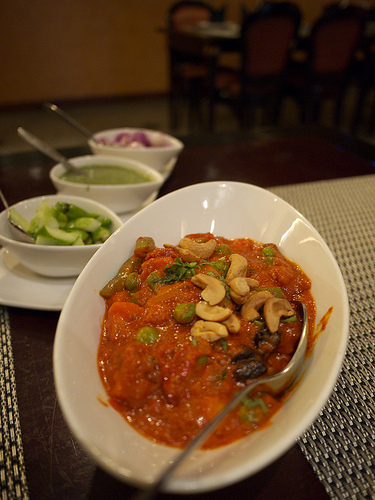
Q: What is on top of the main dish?
A: Cashews.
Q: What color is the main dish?
A: Red.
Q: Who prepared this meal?
A: A Chef.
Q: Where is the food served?
A: A restaurant.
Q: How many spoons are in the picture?
A: 4.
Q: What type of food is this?
A: Thai.